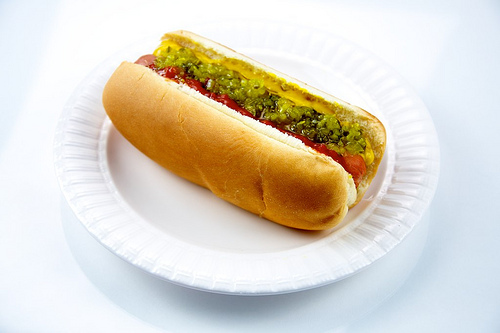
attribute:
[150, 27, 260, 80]
mustard — yellow 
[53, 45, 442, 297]
plate — white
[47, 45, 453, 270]
paper plate — white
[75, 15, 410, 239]
hotdog — delicious 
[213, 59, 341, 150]
relish — Green , sweet 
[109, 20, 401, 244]
bun — brown 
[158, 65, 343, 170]
ketchup — red 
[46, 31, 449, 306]
plate — white 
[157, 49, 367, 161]
relish — green 